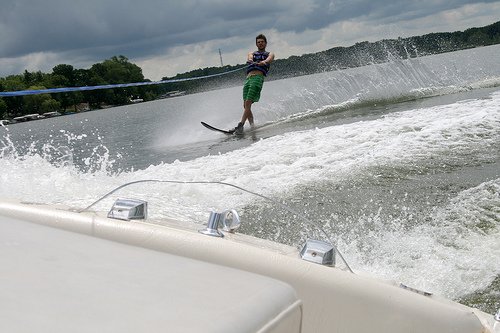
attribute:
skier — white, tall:
[230, 32, 273, 134]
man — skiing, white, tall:
[209, 18, 303, 140]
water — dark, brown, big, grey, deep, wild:
[3, 65, 500, 295]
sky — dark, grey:
[0, 6, 498, 63]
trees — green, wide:
[3, 0, 487, 108]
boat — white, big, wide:
[7, 200, 497, 332]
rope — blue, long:
[1, 47, 266, 115]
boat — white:
[4, 184, 498, 326]